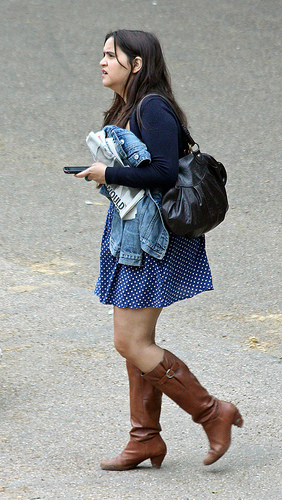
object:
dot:
[102, 258, 104, 261]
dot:
[147, 259, 150, 261]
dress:
[94, 183, 214, 310]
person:
[74, 28, 244, 470]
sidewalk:
[0, 0, 281, 500]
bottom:
[151, 455, 164, 471]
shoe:
[100, 359, 166, 472]